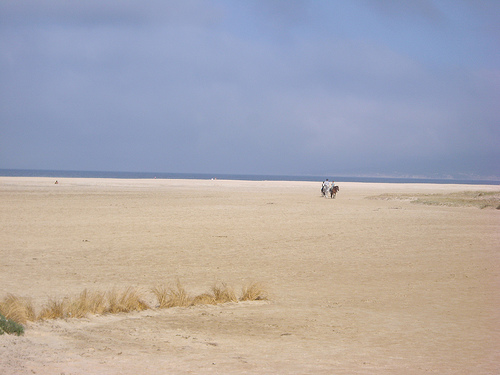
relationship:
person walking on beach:
[318, 179, 327, 189] [2, 176, 499, 374]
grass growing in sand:
[2, 279, 268, 336] [2, 184, 499, 373]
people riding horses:
[312, 184, 345, 201] [314, 163, 358, 209]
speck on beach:
[52, 178, 59, 185] [2, 176, 499, 374]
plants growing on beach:
[23, 275, 277, 317] [88, 170, 256, 273]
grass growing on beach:
[4, 281, 272, 327] [5, 188, 475, 285]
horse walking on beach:
[327, 181, 339, 196] [2, 176, 499, 374]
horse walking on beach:
[317, 184, 329, 197] [2, 176, 499, 374]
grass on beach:
[2, 279, 268, 336] [2, 176, 499, 374]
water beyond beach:
[2, 167, 498, 186] [2, 176, 499, 374]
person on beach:
[329, 177, 334, 190] [2, 176, 499, 374]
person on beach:
[318, 179, 327, 189] [2, 176, 499, 374]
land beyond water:
[304, 170, 499, 182] [2, 167, 498, 186]